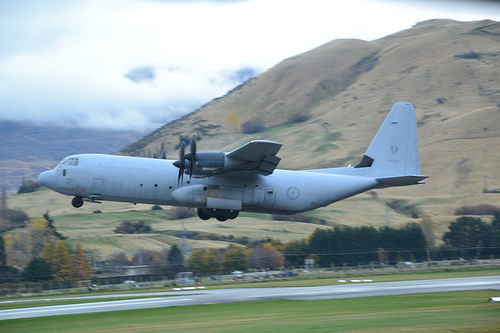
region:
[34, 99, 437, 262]
A gray plane taking off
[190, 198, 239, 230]
Wheels in middle of plane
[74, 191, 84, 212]
Wheel on front of plane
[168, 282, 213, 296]
White lines with red marks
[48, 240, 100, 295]
Yellow and orange tree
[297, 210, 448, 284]
Row of green trees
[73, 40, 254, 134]
white clouds in the sky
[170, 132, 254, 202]
two dark gray propellers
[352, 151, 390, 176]
Black area on tail of plane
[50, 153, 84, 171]
windshield of a plane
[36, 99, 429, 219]
The airplane is taking off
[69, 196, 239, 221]
landing gear is retracting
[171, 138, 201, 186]
the engines are propellers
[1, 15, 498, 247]
The mountain is behind the plane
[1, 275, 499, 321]
Runway is under plane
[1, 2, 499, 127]
sky is cloudy and blue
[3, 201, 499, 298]
trees behind fence line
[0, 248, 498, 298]
Cars behind fence line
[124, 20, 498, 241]
Large brown mountainside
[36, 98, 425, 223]
The airplane is grey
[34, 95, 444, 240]
A plane is taking off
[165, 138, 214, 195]
Two propellers on the plane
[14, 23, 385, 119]
White clouds in the sky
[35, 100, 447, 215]
Dark gray propellers on light gray plane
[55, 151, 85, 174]
Windshield of plane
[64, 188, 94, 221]
front tire of plane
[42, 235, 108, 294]
Yellow and orange tree on the ground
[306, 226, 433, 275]
Row of dark green trees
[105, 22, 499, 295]
Tan mountain on side of plane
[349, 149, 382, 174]
Black area on back of plane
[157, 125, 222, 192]
The propellers on the plane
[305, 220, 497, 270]
Trees beside the runway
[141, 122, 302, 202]
A wing on a plane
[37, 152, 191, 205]
The front of the plane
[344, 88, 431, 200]
The tail end of the plane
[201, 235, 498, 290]
Power lines along the side of the air strip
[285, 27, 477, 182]
The mountain is bare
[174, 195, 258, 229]
The wheels for the plane to land on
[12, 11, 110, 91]
The sky is full of clouds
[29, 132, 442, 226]
The plane is grey.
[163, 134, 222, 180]
The propellers are grey.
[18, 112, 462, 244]
The plane is taking off.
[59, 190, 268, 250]
The wheels are down.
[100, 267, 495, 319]
The runway is long.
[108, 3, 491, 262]
The mountain is tall.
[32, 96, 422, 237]
The plane is large.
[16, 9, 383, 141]
The clouds are thick.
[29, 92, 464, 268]
The plane is in the air.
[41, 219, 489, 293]
The trees are leafy.